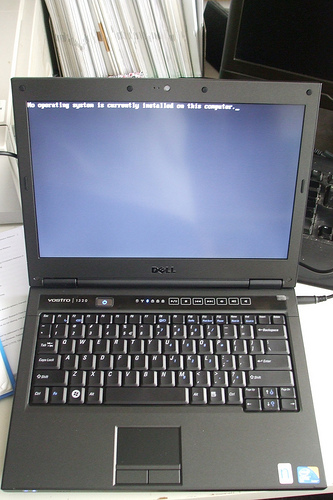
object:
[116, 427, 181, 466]
mousepad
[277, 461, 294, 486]
sticker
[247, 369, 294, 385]
key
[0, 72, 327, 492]
computer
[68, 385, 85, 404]
windows key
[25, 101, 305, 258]
monitor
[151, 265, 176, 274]
dell logo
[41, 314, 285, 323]
row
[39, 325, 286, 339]
row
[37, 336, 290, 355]
row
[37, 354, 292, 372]
row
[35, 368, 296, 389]
row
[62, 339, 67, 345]
q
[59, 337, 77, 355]
key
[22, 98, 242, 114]
message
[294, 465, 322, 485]
sticker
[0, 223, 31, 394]
papers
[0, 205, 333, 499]
table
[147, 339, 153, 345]
y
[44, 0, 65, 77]
booklets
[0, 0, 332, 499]
desk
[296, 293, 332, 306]
plug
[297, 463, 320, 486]
windows symbol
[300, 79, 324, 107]
corner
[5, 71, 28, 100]
corner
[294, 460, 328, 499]
corner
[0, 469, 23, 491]
corner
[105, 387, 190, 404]
spacebar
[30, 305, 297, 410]
keyboard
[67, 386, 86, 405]
windows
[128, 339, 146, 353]
key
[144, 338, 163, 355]
key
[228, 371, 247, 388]
key